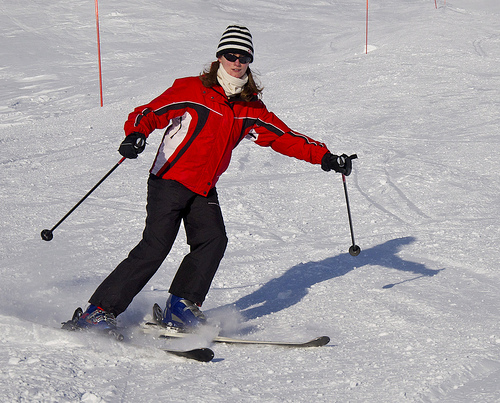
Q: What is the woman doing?
A: Skiing.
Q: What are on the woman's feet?
A: A pair of skis.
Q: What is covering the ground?
A: White snow.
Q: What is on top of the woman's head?
A: A striped hat.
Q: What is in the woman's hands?
A: Ski poles.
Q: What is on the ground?
A: Snow.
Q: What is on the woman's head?
A: Hat.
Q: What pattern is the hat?
A: Striped.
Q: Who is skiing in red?
A: The woman.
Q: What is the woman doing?
A: Skiing.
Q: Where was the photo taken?
A: Slope.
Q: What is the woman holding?
A: Poles.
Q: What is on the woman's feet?
A: Skis.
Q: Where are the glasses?
A: Woman's face.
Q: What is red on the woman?
A: Coat.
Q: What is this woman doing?
A: Skiing.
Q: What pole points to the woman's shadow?
A: Left.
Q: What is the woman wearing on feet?
A: Skis.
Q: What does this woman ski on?
A: Snow.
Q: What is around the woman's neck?
A: White scarf.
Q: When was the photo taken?
A: Daytime.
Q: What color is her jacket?
A: Red.